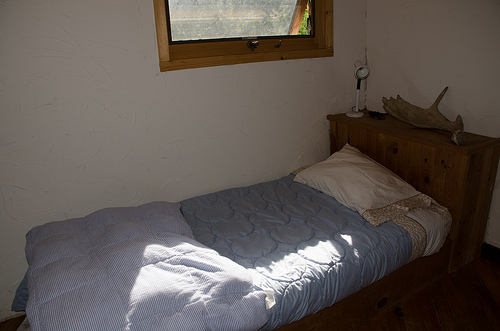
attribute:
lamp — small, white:
[347, 62, 371, 120]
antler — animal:
[377, 84, 461, 141]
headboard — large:
[323, 109, 481, 245]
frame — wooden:
[157, 34, 331, 71]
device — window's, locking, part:
[247, 34, 260, 47]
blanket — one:
[273, 210, 359, 300]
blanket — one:
[27, 197, 219, 327]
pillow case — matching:
[295, 141, 436, 226]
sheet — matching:
[404, 210, 451, 258]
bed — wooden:
[12, 104, 484, 330]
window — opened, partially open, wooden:
[146, 0, 334, 74]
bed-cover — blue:
[181, 180, 426, 329]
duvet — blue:
[9, 202, 279, 328]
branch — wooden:
[379, 86, 461, 145]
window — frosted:
[155, 1, 335, 70]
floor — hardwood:
[385, 294, 485, 326]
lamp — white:
[345, 65, 372, 115]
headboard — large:
[321, 114, 484, 264]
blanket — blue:
[20, 200, 267, 329]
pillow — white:
[289, 134, 438, 226]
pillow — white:
[292, 141, 437, 226]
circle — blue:
[266, 184, 303, 209]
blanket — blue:
[24, 163, 407, 328]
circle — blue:
[287, 194, 320, 221]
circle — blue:
[314, 211, 346, 236]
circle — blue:
[330, 222, 372, 250]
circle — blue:
[270, 218, 315, 241]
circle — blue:
[250, 203, 290, 229]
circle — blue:
[230, 190, 275, 211]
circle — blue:
[260, 247, 314, 281]